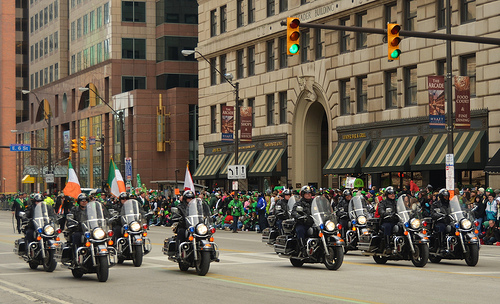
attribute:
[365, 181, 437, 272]
plane — white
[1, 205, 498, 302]
road — grey, tarmac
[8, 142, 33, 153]
sign — blue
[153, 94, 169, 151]
plane — white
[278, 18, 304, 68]
light — green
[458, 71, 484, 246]
plane — white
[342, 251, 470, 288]
tarmac — grey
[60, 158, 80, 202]
flag — green, white, orange